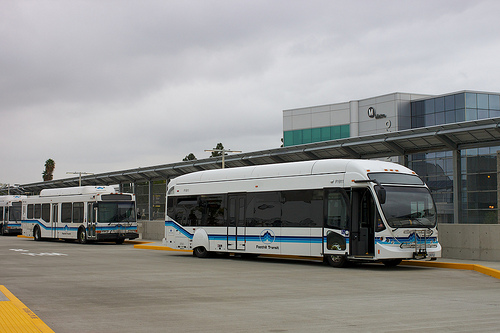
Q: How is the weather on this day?
A: It is cloudy.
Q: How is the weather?
A: It is cloudy.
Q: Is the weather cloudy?
A: Yes, it is cloudy.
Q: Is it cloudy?
A: Yes, it is cloudy.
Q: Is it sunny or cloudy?
A: It is cloudy.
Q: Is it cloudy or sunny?
A: It is cloudy.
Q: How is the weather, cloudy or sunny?
A: It is cloudy.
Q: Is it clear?
A: No, it is cloudy.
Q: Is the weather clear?
A: No, it is cloudy.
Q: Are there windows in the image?
A: Yes, there are windows.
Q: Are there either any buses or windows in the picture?
A: Yes, there are windows.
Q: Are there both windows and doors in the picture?
A: Yes, there are both windows and a door.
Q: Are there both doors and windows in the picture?
A: Yes, there are both windows and a door.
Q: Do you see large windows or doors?
A: Yes, there are large windows.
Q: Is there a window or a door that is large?
A: Yes, the windows are large.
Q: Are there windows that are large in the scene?
A: Yes, there are large windows.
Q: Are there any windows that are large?
A: Yes, there are windows that are large.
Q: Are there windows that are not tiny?
A: Yes, there are large windows.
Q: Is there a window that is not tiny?
A: Yes, there are large windows.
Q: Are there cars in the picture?
A: No, there are no cars.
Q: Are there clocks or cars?
A: No, there are no cars or clocks.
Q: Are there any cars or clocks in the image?
A: No, there are no cars or clocks.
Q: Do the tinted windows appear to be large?
A: Yes, the windows are large.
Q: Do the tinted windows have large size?
A: Yes, the windows are large.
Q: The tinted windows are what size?
A: The windows are large.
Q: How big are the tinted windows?
A: The windows are large.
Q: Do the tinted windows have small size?
A: No, the windows are large.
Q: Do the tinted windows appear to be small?
A: No, the windows are large.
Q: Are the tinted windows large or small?
A: The windows are large.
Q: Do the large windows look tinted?
A: Yes, the windows are tinted.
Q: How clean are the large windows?
A: The windows are tinted.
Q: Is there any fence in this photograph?
A: No, there are no fences.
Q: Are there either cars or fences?
A: No, there are no fences or cars.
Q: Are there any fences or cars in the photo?
A: No, there are no fences or cars.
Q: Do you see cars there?
A: No, there are no cars.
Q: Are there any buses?
A: Yes, there is a bus.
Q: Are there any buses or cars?
A: Yes, there is a bus.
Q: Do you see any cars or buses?
A: Yes, there is a bus.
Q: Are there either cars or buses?
A: Yes, there is a bus.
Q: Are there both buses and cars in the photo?
A: No, there is a bus but no cars.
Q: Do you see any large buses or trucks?
A: Yes, there is a large bus.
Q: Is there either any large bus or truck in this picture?
A: Yes, there is a large bus.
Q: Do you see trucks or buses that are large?
A: Yes, the bus is large.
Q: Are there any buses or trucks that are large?
A: Yes, the bus is large.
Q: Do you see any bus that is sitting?
A: Yes, there is a bus that is sitting.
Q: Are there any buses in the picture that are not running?
A: Yes, there is a bus that is sitting.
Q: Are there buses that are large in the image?
A: Yes, there is a large bus.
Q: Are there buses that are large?
A: Yes, there is a bus that is large.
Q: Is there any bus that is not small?
A: Yes, there is a large bus.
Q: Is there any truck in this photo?
A: No, there are no trucks.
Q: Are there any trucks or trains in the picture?
A: No, there are no trucks or trains.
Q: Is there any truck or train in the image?
A: No, there are no trucks or trains.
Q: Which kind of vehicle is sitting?
A: The vehicle is a bus.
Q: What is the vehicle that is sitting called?
A: The vehicle is a bus.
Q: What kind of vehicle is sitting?
A: The vehicle is a bus.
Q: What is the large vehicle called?
A: The vehicle is a bus.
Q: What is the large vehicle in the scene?
A: The vehicle is a bus.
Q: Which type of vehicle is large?
A: The vehicle is a bus.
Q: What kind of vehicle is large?
A: The vehicle is a bus.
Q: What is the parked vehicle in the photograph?
A: The vehicle is a bus.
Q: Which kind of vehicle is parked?
A: The vehicle is a bus.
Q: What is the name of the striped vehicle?
A: The vehicle is a bus.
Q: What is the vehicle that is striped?
A: The vehicle is a bus.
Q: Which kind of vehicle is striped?
A: The vehicle is a bus.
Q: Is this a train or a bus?
A: This is a bus.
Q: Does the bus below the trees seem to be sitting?
A: Yes, the bus is sitting.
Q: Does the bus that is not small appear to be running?
A: No, the bus is sitting.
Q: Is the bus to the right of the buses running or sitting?
A: The bus is sitting.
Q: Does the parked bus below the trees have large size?
A: Yes, the bus is large.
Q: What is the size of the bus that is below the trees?
A: The bus is large.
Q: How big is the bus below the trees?
A: The bus is large.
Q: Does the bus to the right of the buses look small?
A: No, the bus is large.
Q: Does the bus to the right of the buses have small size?
A: No, the bus is large.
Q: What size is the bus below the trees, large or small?
A: The bus is large.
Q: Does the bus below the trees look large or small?
A: The bus is large.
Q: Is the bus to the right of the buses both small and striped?
A: No, the bus is striped but large.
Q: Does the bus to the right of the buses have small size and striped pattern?
A: No, the bus is striped but large.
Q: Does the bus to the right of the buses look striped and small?
A: No, the bus is striped but large.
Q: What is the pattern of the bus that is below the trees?
A: The bus is striped.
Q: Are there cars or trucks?
A: No, there are no cars or trucks.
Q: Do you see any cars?
A: No, there are no cars.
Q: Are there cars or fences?
A: No, there are no cars or fences.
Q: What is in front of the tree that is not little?
A: The building is in front of the tree.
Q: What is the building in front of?
A: The building is in front of the tree.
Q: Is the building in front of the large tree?
A: Yes, the building is in front of the tree.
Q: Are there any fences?
A: No, there are no fences.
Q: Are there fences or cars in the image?
A: No, there are no fences or cars.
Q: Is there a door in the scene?
A: Yes, there is a door.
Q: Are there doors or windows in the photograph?
A: Yes, there is a door.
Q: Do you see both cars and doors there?
A: No, there is a door but no cars.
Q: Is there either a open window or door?
A: Yes, there is an open door.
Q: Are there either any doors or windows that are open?
A: Yes, the door is open.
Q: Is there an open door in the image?
A: Yes, there is an open door.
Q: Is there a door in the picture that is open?
A: Yes, there is a door that is open.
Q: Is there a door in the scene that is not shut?
A: Yes, there is a open door.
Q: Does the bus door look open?
A: Yes, the door is open.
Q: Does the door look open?
A: Yes, the door is open.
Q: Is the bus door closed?
A: No, the door is open.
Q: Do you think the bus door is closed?
A: No, the door is open.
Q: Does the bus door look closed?
A: No, the door is open.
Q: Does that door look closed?
A: No, the door is open.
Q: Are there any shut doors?
A: No, there is a door but it is open.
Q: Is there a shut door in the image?
A: No, there is a door but it is open.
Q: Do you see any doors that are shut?
A: No, there is a door but it is open.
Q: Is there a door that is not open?
A: No, there is a door but it is open.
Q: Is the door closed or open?
A: The door is open.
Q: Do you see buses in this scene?
A: Yes, there are buses.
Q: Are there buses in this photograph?
A: Yes, there are buses.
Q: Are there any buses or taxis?
A: Yes, there are buses.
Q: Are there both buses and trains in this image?
A: No, there are buses but no trains.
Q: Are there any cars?
A: No, there are no cars.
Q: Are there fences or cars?
A: No, there are no cars or fences.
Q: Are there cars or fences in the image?
A: No, there are no cars or fences.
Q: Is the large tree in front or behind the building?
A: The tree is behind the building.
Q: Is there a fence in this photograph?
A: No, there are no fences.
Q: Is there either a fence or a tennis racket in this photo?
A: No, there are no fences or rackets.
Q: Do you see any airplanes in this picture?
A: No, there are no airplanes.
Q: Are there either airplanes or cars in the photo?
A: No, there are no airplanes or cars.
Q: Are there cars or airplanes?
A: No, there are no airplanes or cars.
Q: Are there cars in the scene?
A: No, there are no cars.